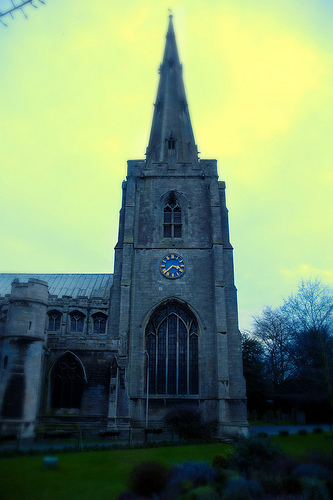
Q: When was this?
A: Daytime.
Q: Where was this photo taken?
A: At a church.